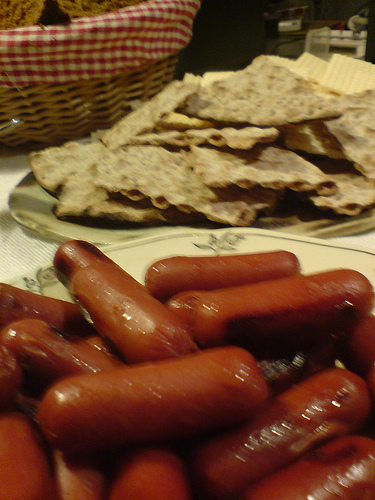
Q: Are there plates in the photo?
A: Yes, there is a plate.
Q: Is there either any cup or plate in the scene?
A: Yes, there is a plate.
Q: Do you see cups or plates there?
A: Yes, there is a plate.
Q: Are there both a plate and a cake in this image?
A: No, there is a plate but no cakes.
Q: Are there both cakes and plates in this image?
A: No, there is a plate but no cakes.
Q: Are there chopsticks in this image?
A: No, there are no chopsticks.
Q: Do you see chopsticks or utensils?
A: No, there are no chopsticks or utensils.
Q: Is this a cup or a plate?
A: This is a plate.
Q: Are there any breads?
A: Yes, there is a bread.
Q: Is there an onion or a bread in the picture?
A: Yes, there is a bread.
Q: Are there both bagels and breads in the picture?
A: No, there is a bread but no bagels.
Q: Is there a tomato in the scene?
A: No, there are no tomatoes.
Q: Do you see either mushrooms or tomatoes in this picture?
A: No, there are no tomatoes or mushrooms.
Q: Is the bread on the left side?
A: Yes, the bread is on the left of the image.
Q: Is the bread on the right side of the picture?
A: No, the bread is on the left of the image.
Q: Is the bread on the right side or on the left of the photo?
A: The bread is on the left of the image.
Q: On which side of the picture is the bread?
A: The bread is on the left of the image.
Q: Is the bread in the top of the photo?
A: Yes, the bread is in the top of the image.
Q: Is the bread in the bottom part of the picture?
A: No, the bread is in the top of the image.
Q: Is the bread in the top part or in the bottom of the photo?
A: The bread is in the top of the image.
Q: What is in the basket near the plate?
A: The bread is in the basket.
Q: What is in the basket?
A: The bread is in the basket.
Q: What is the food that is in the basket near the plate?
A: The food is a bread.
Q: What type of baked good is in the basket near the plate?
A: The food is a bread.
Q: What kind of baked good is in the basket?
A: The food is a bread.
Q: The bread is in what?
A: The bread is in the basket.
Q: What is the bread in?
A: The bread is in the basket.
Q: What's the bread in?
A: The bread is in the basket.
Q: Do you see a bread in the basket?
A: Yes, there is a bread in the basket.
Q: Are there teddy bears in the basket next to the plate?
A: No, there is a bread in the basket.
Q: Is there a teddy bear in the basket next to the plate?
A: No, there is a bread in the basket.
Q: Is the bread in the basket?
A: Yes, the bread is in the basket.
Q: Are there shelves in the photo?
A: No, there are no shelves.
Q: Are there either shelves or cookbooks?
A: No, there are no shelves or cookbooks.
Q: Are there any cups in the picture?
A: No, there are no cups.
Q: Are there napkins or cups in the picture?
A: No, there are no cups or napkins.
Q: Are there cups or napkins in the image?
A: No, there are no cups or napkins.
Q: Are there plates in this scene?
A: Yes, there is a plate.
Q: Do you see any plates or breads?
A: Yes, there is a plate.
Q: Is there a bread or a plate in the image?
A: Yes, there is a plate.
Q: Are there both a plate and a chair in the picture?
A: Yes, there are both a plate and a chair.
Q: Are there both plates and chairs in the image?
A: Yes, there are both a plate and a chair.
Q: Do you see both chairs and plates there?
A: Yes, there are both a plate and a chair.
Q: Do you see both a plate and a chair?
A: Yes, there are both a plate and a chair.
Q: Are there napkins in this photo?
A: No, there are no napkins.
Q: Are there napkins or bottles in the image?
A: No, there are no napkins or bottles.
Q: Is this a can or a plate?
A: This is a plate.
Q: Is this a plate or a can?
A: This is a plate.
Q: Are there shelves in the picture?
A: No, there are no shelves.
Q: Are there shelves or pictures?
A: No, there are no shelves or pictures.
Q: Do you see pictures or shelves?
A: No, there are no shelves or pictures.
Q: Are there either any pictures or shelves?
A: No, there are no shelves or pictures.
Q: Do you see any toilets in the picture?
A: No, there are no toilets.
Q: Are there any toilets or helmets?
A: No, there are no toilets or helmets.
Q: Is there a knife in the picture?
A: No, there are no knives.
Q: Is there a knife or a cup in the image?
A: No, there are no knives or cups.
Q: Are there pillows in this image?
A: No, there are no pillows.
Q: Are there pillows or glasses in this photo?
A: No, there are no pillows or glasses.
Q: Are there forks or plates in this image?
A: Yes, there is a plate.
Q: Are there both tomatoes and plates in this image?
A: No, there is a plate but no tomatoes.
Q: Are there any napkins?
A: No, there are no napkins.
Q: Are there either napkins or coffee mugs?
A: No, there are no napkins or coffee mugs.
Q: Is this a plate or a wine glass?
A: This is a plate.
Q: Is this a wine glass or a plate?
A: This is a plate.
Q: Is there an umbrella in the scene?
A: No, there are no umbrellas.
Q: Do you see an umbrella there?
A: No, there are no umbrellas.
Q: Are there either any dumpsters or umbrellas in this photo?
A: No, there are no umbrellas or dumpsters.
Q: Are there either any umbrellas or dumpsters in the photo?
A: No, there are no umbrellas or dumpsters.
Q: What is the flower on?
A: The flower is on the platter.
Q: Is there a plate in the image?
A: Yes, there is a plate.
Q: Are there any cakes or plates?
A: Yes, there is a plate.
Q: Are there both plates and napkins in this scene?
A: No, there is a plate but no napkins.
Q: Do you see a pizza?
A: No, there are no pizzas.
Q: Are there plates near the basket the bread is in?
A: Yes, there is a plate near the basket.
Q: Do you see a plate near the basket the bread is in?
A: Yes, there is a plate near the basket.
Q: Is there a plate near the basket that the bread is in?
A: Yes, there is a plate near the basket.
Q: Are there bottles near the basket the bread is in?
A: No, there is a plate near the basket.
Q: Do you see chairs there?
A: Yes, there is a chair.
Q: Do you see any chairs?
A: Yes, there is a chair.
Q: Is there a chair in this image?
A: Yes, there is a chair.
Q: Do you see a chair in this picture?
A: Yes, there is a chair.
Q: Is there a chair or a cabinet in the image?
A: Yes, there is a chair.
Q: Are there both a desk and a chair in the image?
A: No, there is a chair but no desks.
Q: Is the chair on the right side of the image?
A: Yes, the chair is on the right of the image.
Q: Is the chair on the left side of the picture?
A: No, the chair is on the right of the image.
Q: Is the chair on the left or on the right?
A: The chair is on the right of the image.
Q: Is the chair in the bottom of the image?
A: No, the chair is in the top of the image.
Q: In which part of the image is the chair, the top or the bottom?
A: The chair is in the top of the image.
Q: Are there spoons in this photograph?
A: No, there are no spoons.